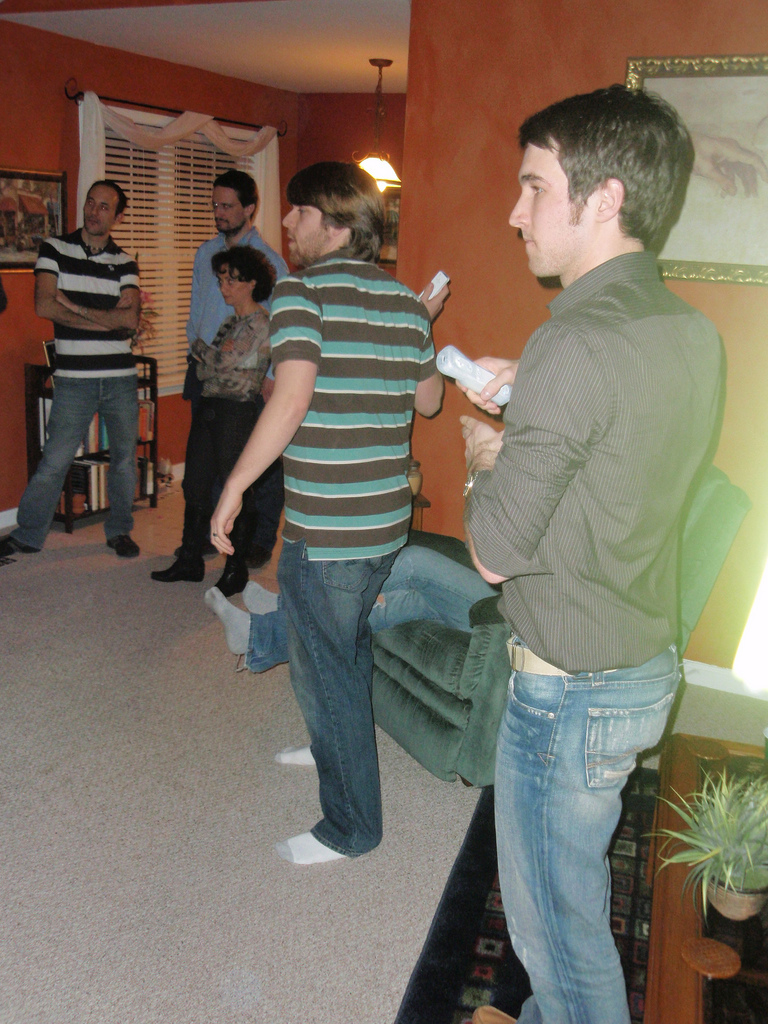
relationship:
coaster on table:
[681, 934, 741, 974] [660, 960, 697, 999]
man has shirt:
[210, 159, 447, 865] [269, 247, 439, 563]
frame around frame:
[622, 51, 765, 285] [625, 54, 764, 286]